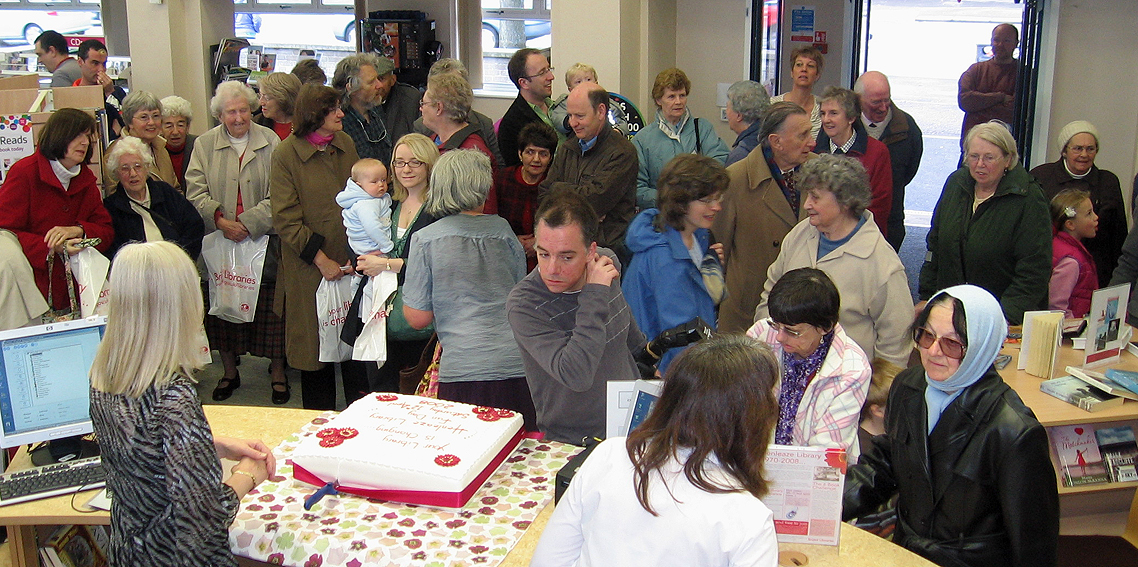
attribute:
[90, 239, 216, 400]
hair — blonde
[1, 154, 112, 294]
coat — red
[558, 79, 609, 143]
head — balding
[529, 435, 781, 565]
shirt — white